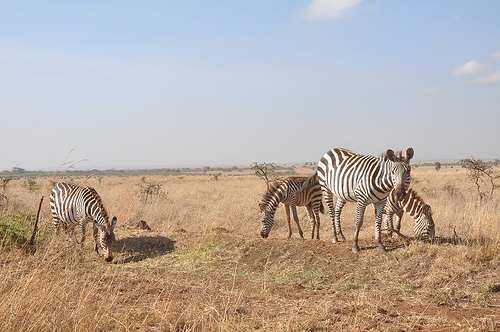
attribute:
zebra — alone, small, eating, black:
[52, 182, 121, 260]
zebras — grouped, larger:
[242, 140, 444, 255]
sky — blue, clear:
[112, 22, 357, 76]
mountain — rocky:
[6, 162, 33, 177]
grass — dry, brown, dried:
[38, 274, 269, 324]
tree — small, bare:
[252, 156, 287, 202]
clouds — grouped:
[320, 5, 491, 99]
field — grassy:
[101, 186, 348, 319]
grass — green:
[0, 199, 50, 257]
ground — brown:
[216, 225, 451, 318]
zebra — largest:
[319, 147, 410, 246]